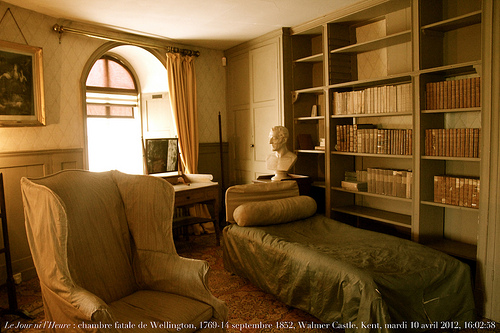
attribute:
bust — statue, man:
[266, 125, 297, 181]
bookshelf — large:
[288, 0, 493, 317]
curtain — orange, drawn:
[165, 52, 216, 236]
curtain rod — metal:
[52, 23, 200, 57]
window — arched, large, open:
[85, 55, 143, 175]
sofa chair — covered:
[222, 180, 474, 333]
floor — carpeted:
[0, 230, 500, 333]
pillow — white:
[233, 195, 317, 226]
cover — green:
[222, 213, 474, 333]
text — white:
[4, 320, 495, 330]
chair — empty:
[20, 169, 229, 333]